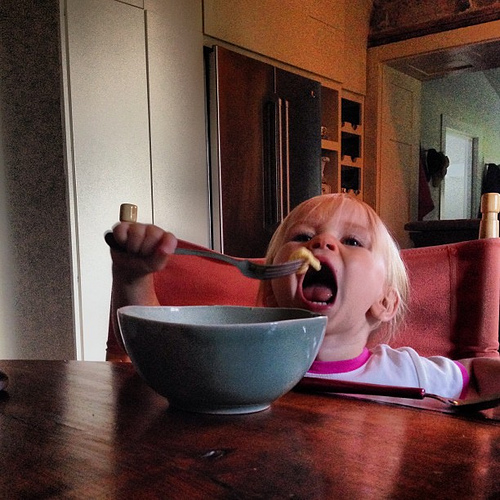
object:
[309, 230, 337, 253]
nose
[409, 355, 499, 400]
arm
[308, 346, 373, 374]
collar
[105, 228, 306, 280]
fork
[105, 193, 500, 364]
chair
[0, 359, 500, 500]
table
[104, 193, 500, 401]
boy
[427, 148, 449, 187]
brown hat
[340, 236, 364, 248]
eye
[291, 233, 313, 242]
eye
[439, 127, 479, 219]
doorway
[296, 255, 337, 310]
mouth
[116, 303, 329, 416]
bowl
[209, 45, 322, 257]
refrigerator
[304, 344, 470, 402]
shirt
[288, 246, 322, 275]
food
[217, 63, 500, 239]
background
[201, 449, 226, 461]
knot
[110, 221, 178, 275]
hand